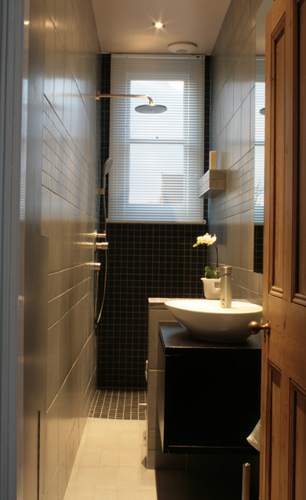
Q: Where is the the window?
A: On the wall.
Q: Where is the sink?
A: On the bathroom vanity.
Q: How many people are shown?
A: None.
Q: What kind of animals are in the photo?
A: None.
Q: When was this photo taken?
A: Daytime.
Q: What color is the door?
A: Brown.